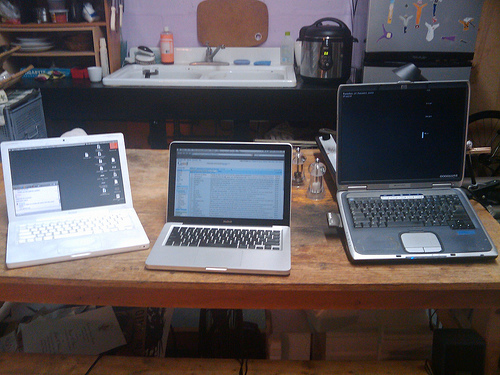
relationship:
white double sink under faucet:
[112, 40, 295, 101] [201, 39, 230, 60]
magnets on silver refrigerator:
[377, 4, 484, 51] [365, 0, 477, 83]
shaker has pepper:
[292, 150, 306, 188] [288, 172, 306, 184]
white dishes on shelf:
[11, 30, 60, 55] [1, 4, 108, 84]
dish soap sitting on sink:
[180, 47, 232, 72] [105, 44, 298, 88]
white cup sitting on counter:
[83, 60, 106, 84] [25, 66, 155, 98]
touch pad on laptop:
[397, 230, 445, 254] [327, 75, 498, 265]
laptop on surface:
[5, 129, 154, 264] [2, 127, 495, 320]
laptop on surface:
[143, 135, 294, 277] [2, 127, 495, 320]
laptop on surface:
[327, 75, 498, 265] [2, 127, 495, 320]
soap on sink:
[231, 53, 272, 71] [104, 41, 299, 91]